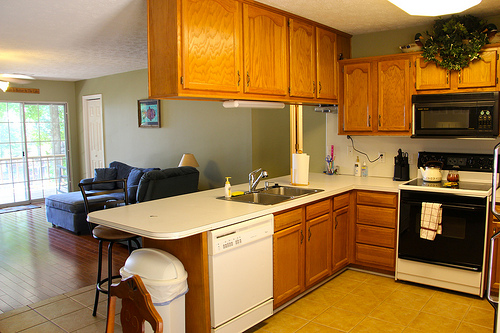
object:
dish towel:
[419, 201, 442, 241]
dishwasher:
[207, 213, 273, 333]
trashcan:
[118, 247, 190, 332]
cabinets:
[239, 1, 288, 100]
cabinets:
[304, 192, 333, 291]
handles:
[237, 69, 241, 85]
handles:
[318, 81, 322, 94]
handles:
[368, 115, 371, 127]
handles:
[300, 229, 304, 243]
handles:
[445, 70, 449, 84]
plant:
[417, 13, 490, 71]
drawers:
[354, 191, 396, 271]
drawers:
[333, 193, 350, 275]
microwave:
[410, 91, 498, 139]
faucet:
[248, 167, 269, 192]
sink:
[217, 185, 324, 205]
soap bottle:
[224, 176, 232, 197]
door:
[80, 95, 105, 179]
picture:
[134, 96, 164, 129]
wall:
[74, 69, 253, 191]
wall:
[250, 103, 325, 181]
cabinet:
[180, 0, 246, 97]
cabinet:
[289, 14, 317, 103]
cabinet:
[336, 57, 411, 136]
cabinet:
[273, 209, 306, 304]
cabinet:
[411, 47, 452, 90]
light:
[386, 0, 482, 18]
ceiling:
[259, 0, 499, 35]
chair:
[101, 274, 165, 332]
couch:
[44, 160, 199, 250]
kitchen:
[88, 1, 499, 333]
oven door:
[397, 186, 487, 273]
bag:
[118, 266, 187, 304]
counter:
[86, 170, 410, 240]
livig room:
[0, 1, 252, 315]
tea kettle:
[419, 161, 443, 183]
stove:
[401, 176, 491, 193]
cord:
[345, 135, 382, 162]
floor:
[240, 269, 494, 331]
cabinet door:
[180, 1, 240, 93]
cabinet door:
[242, 2, 288, 96]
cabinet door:
[288, 16, 315, 100]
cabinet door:
[373, 55, 411, 133]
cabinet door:
[316, 27, 339, 103]